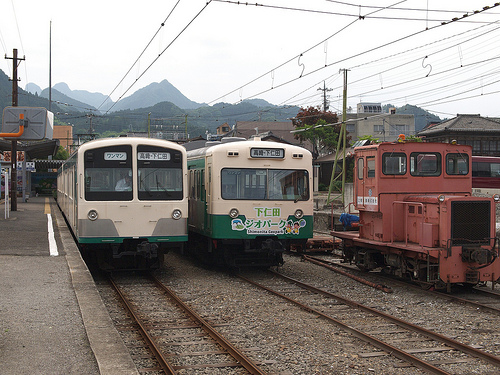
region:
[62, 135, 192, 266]
the train on the tracks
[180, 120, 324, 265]
the train on the tracks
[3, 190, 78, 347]
the platform beside the train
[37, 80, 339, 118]
mountains in the background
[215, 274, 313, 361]
gravel beside the tracks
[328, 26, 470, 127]
power cables above the train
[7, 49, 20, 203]
wooden pole on the platform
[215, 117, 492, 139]
buildings in the background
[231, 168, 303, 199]
windshield on the train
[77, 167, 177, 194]
windshield on the train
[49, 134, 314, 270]
two electric trains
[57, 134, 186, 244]
green and white rail cars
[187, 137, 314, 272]
green and cream colored rail car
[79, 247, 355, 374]
train tracks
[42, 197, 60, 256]
warning stripes painted on platform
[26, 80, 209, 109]
distant mountains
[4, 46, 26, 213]
wooden utility pole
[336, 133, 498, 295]
small train work engine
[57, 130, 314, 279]
passenger trains at a rural train station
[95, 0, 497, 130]
exterior electrical wires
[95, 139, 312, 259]
these are two trains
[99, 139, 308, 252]
the trains are motionless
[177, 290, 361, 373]
these are the rails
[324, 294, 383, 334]
the rails are rusty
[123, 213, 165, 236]
the front is white in color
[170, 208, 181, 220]
the light is off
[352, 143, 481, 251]
the train is short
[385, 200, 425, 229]
the train is red in color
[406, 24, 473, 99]
these are electric lines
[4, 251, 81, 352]
this is the pavement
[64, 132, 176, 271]
this is a train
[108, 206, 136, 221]
the train is white in color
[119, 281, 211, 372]
this is a railway line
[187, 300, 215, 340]
this is a metal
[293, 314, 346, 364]
these are small rocks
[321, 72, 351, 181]
this is a pole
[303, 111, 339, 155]
this is a tree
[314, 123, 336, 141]
the leaves are green in color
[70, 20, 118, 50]
this is the sky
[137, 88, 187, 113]
this is a mountain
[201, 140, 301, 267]
this is a train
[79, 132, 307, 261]
the trains are two in color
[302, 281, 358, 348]
this is the railway line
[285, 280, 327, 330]
this is a metal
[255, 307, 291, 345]
this are small stones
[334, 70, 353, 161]
this is a pole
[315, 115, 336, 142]
this is a tree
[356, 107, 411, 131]
this is a building